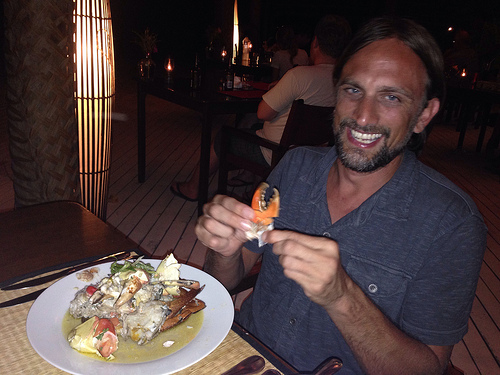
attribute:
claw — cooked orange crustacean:
[251, 183, 281, 242]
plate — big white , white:
[26, 257, 230, 373]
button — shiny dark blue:
[341, 257, 445, 342]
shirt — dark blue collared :
[277, 144, 462, 358]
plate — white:
[36, 240, 225, 369]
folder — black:
[0, 187, 157, 292]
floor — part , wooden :
[102, 92, 499, 371]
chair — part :
[215, 102, 326, 192]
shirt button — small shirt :
[366, 282, 377, 292]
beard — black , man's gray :
[327, 113, 419, 172]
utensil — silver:
[3, 250, 103, 320]